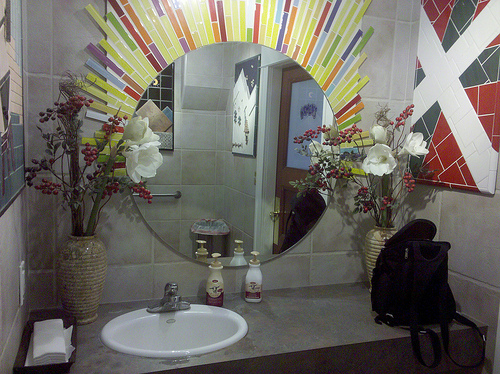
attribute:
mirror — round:
[123, 41, 342, 270]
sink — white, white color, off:
[100, 302, 248, 359]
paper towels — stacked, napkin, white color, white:
[24, 318, 75, 367]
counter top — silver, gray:
[13, 281, 488, 374]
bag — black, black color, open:
[371, 218, 488, 369]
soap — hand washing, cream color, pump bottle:
[204, 252, 223, 307]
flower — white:
[120, 140, 164, 184]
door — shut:
[271, 62, 325, 254]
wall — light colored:
[27, 1, 415, 312]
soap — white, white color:
[243, 251, 263, 304]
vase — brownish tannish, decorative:
[55, 233, 109, 326]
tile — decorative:
[458, 57, 490, 90]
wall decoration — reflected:
[230, 52, 262, 158]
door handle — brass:
[268, 209, 279, 223]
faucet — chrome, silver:
[146, 281, 191, 315]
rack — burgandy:
[12, 308, 78, 372]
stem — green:
[84, 156, 116, 237]